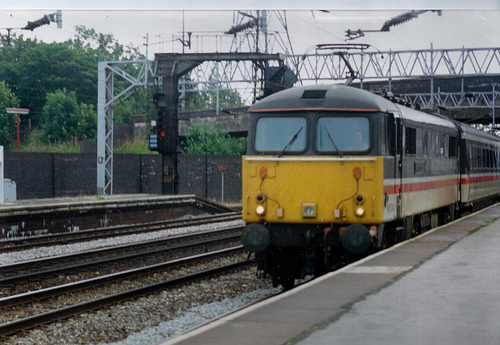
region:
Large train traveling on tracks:
[227, 68, 457, 246]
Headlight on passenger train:
[240, 190, 275, 225]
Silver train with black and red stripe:
[400, 102, 452, 222]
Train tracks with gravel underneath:
[45, 252, 188, 312]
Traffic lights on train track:
[153, 115, 171, 159]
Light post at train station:
[6, 92, 33, 159]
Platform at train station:
[301, 232, 484, 339]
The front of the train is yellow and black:
[247, 90, 391, 245]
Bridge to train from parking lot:
[408, 61, 498, 112]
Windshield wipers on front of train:
[276, 119, 347, 167]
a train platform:
[308, 203, 495, 341]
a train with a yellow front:
[211, 83, 413, 250]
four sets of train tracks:
[14, 202, 206, 339]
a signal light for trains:
[151, 95, 176, 166]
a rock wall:
[23, 151, 218, 191]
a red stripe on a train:
[343, 127, 481, 225]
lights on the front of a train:
[237, 175, 377, 230]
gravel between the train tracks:
[98, 248, 223, 329]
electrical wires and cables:
[12, 10, 448, 69]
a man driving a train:
[276, 82, 381, 210]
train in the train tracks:
[205, 72, 399, 342]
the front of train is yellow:
[225, 134, 415, 236]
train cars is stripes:
[389, 89, 499, 219]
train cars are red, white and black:
[381, 105, 473, 227]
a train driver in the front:
[323, 111, 383, 182]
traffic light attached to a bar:
[124, 83, 179, 179]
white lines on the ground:
[223, 265, 365, 343]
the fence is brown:
[32, 141, 239, 208]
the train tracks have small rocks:
[14, 218, 196, 333]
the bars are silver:
[70, 45, 497, 190]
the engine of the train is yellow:
[237, 82, 464, 267]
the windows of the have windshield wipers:
[253, 112, 371, 159]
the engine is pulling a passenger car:
[245, 91, 499, 241]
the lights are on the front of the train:
[246, 177, 380, 229]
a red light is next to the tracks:
[154, 115, 179, 157]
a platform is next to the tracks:
[6, 184, 238, 290]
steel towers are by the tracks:
[91, 37, 277, 240]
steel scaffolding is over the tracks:
[101, 43, 499, 202]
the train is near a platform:
[145, 192, 499, 343]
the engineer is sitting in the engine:
[244, 118, 383, 215]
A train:
[258, 48, 440, 274]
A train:
[251, 97, 333, 197]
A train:
[276, 103, 351, 329]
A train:
[311, 173, 363, 341]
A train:
[258, 78, 331, 287]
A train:
[262, 166, 325, 301]